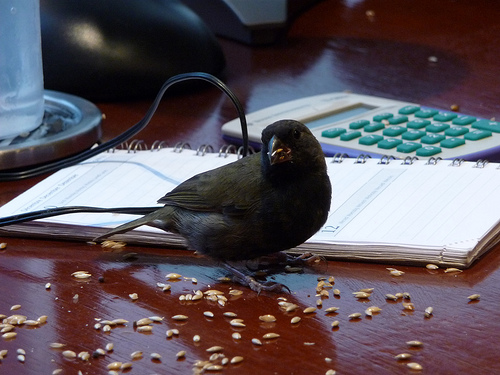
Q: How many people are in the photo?
A: None.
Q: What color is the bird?
A: Black.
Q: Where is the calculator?
A: Behind the calendar.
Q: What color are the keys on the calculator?
A: Green.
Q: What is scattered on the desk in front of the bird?
A: Seeds.